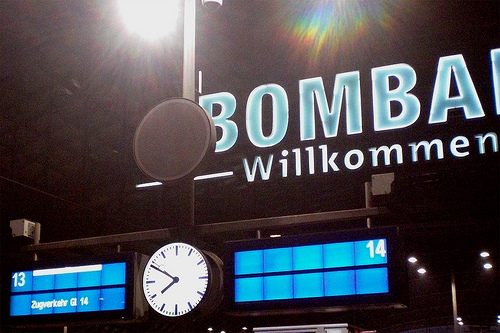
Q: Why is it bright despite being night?
A: Outdoor lights.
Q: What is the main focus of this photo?
A: A clock and sign.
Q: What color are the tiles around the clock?
A: Blue.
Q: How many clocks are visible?
A: One.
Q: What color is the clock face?
A: White.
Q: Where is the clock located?
A: Between the blue tiles.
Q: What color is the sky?
A: Black.